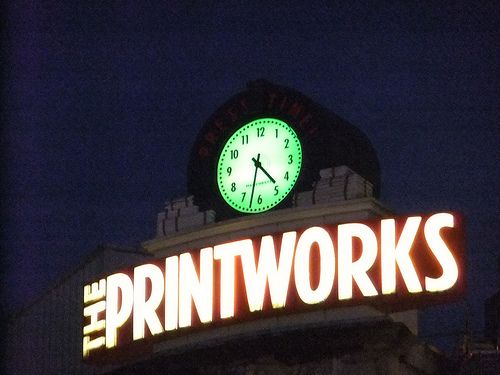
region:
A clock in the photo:
[212, 115, 306, 212]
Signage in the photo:
[65, 207, 470, 360]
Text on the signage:
[83, 200, 470, 351]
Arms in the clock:
[251, 144, 274, 201]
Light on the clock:
[219, 120, 300, 206]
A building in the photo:
[150, 223, 395, 373]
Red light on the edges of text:
[55, 202, 487, 349]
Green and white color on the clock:
[190, 114, 310, 218]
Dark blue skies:
[82, 67, 132, 133]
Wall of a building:
[37, 283, 77, 373]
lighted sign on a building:
[53, 221, 453, 321]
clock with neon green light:
[207, 103, 300, 218]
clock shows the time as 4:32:
[211, 125, 303, 217]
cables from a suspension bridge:
[43, 215, 128, 373]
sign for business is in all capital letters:
[74, 239, 449, 326]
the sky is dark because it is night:
[43, 29, 440, 236]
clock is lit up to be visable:
[219, 108, 301, 216]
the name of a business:
[74, 224, 440, 324]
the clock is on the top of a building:
[211, 107, 350, 205]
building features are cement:
[149, 190, 320, 260]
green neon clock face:
[214, 118, 303, 218]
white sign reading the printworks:
[79, 211, 458, 352]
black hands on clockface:
[245, 151, 278, 206]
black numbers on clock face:
[215, 118, 295, 205]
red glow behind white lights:
[80, 208, 460, 345]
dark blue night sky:
[1, 0, 493, 335]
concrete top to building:
[121, 196, 414, 339]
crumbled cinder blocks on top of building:
[345, 315, 450, 370]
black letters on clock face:
[242, 175, 268, 188]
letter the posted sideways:
[81, 277, 104, 352]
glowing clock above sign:
[181, 90, 333, 217]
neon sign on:
[33, 220, 486, 352]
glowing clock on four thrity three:
[180, 71, 325, 212]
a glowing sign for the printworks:
[23, 207, 489, 353]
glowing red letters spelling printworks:
[104, 207, 458, 349]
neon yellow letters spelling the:
[44, 278, 116, 348]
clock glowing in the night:
[136, 100, 331, 216]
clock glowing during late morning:
[176, 106, 341, 214]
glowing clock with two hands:
[165, 96, 316, 215]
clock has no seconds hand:
[146, 78, 319, 215]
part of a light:
[428, 273, 440, 288]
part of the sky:
[425, 83, 427, 90]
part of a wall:
[283, 162, 291, 177]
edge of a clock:
[282, 165, 293, 187]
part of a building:
[411, 340, 423, 353]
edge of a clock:
[263, 188, 280, 218]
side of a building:
[127, 291, 147, 318]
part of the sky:
[380, 135, 396, 166]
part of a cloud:
[398, 110, 413, 122]